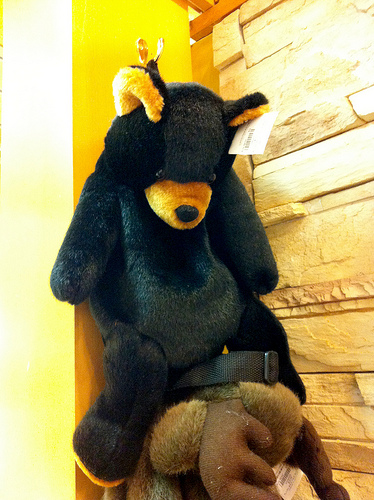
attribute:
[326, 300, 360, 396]
brick — yellow, brown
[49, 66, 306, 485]
teddy bear — black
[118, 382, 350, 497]
moose — brown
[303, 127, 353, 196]
brick —  yellow and brown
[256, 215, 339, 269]
brick — yellow, brown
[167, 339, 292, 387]
strap — thick, black, buckle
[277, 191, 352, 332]
brick — brown, yellow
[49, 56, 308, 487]
bear — black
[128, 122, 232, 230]
face — brown